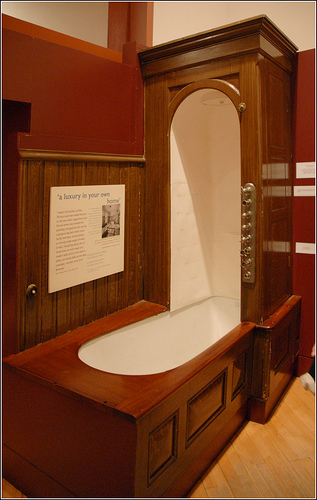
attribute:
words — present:
[50, 182, 121, 204]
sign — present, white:
[43, 178, 136, 297]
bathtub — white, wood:
[73, 305, 256, 383]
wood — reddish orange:
[8, 294, 258, 419]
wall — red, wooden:
[10, 146, 150, 341]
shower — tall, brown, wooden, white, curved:
[150, 66, 250, 329]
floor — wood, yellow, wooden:
[200, 397, 316, 494]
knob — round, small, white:
[23, 279, 43, 306]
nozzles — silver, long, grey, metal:
[237, 182, 258, 287]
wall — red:
[6, 16, 144, 157]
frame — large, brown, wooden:
[7, 15, 309, 491]